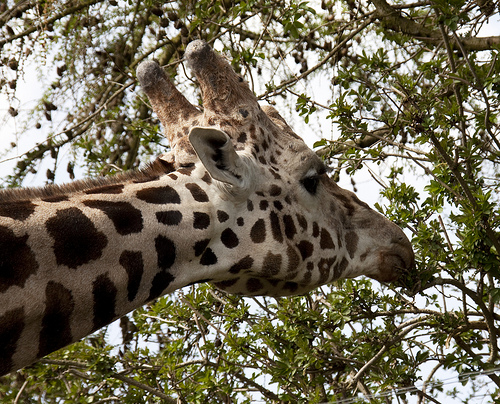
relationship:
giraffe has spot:
[0, 39, 415, 377] [136, 185, 180, 203]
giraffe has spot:
[0, 39, 415, 377] [84, 199, 146, 236]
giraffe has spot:
[0, 39, 415, 377] [45, 206, 110, 270]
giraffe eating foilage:
[0, 39, 415, 377] [374, 167, 458, 275]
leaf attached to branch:
[304, 114, 309, 125] [282, 88, 335, 113]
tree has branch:
[0, 0, 498, 404] [282, 88, 335, 113]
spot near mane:
[136, 185, 180, 203] [0, 157, 177, 203]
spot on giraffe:
[136, 185, 180, 203] [0, 39, 415, 377]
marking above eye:
[315, 162, 328, 175] [299, 174, 321, 196]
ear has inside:
[187, 126, 251, 189] [204, 136, 242, 180]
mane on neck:
[0, 157, 177, 203] [0, 169, 222, 377]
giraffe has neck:
[0, 39, 415, 377] [0, 169, 222, 377]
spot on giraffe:
[84, 199, 146, 236] [0, 39, 415, 377]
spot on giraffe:
[45, 206, 110, 270] [0, 39, 415, 377]